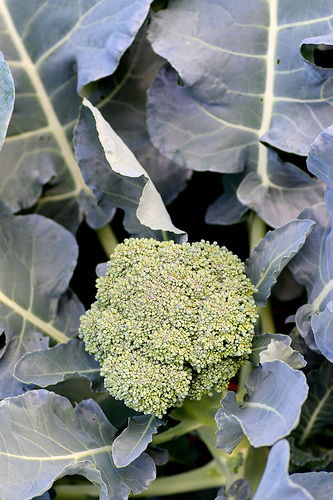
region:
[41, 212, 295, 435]
broccoli starting to grow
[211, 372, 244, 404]
red line under broccoli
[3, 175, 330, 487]
leaves of broccoli plant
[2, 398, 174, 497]
leaves have veins in them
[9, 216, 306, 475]
two shades of green on plant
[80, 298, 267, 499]
Large stem of broccoli plant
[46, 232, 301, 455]
broccoli is light green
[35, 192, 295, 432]
dark spaces between leaves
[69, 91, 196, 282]
the leaf is starting to curl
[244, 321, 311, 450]
underside of leaf is white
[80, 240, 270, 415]
the head of a flower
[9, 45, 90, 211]
a leaf stem of the plant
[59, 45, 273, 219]
purple or blue leaves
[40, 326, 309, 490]
fresh looking plant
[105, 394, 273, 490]
stems and leaves on the plant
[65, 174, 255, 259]
a dark background to the plant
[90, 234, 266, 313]
green, yellow and white colors on the flower head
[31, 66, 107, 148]
barely noticeable spots on the leaves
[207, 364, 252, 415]
something red is in the background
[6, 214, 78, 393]
healthy looking plant leaves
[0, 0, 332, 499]
a broccoli vegetable garden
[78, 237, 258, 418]
a head of broccoli buds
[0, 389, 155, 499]
a broccoli plant leaf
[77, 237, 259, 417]
the broccoli flower head is made up of buds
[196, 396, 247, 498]
the broccoli plant stalk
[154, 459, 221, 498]
the broccoli plant stem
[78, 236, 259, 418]
tight flower buds before they have flowered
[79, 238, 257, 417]
green and yellow broccoli flower buds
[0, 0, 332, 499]
a broccoli vegetable garden ready to harvest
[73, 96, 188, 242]
older leaf curling on the broccoli plant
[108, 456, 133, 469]
edge of a leaf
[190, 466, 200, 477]
edge of a stalk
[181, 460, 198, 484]
part of a stalk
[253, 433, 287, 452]
edge of a leaf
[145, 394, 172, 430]
part of a plant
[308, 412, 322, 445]
part of a leaf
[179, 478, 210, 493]
edge of a stalk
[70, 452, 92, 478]
edge of a leaf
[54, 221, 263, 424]
green part of the tree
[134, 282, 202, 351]
rough looking piece of tree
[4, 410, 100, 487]
leaf on the tree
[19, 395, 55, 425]
lines on the leaf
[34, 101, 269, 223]
many different purple leaves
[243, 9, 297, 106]
big line on the leaf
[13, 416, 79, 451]
many lines on leaf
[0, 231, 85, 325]
one purple leaf among many others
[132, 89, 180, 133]
edge of a purple leaf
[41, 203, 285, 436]
green and purple stuff